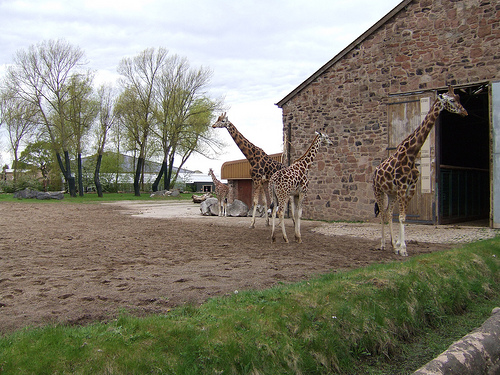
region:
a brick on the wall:
[335, 185, 357, 199]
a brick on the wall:
[337, 199, 342, 206]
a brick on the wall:
[343, 198, 354, 211]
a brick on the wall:
[311, 200, 322, 209]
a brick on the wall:
[317, 197, 331, 209]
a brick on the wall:
[356, 203, 369, 210]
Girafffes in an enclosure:
[209, 83, 466, 255]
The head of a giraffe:
[439, 85, 464, 119]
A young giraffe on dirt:
[260, 130, 334, 238]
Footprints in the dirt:
[13, 271, 153, 312]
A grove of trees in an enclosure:
[4, 38, 212, 196]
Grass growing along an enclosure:
[4, 239, 498, 374]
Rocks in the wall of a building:
[402, 20, 480, 64]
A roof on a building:
[65, 153, 205, 174]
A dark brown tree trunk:
[130, 157, 143, 200]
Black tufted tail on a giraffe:
[370, 200, 381, 222]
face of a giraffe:
[430, 80, 470, 116]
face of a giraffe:
[302, 120, 329, 156]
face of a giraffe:
[202, 105, 243, 130]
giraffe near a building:
[205, 163, 235, 213]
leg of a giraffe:
[391, 202, 414, 255]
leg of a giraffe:
[276, 201, 291, 266]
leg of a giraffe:
[291, 188, 302, 248]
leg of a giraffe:
[247, 186, 262, 229]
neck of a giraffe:
[410, 117, 434, 149]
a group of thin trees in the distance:
[0, 37, 226, 197]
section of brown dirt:
[1, 204, 444, 320]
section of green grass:
[3, 240, 498, 373]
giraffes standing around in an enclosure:
[203, 94, 470, 257]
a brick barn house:
[278, 0, 498, 223]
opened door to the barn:
[383, 85, 498, 225]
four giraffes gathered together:
[203, 90, 468, 257]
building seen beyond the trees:
[33, 153, 200, 183]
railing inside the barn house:
[437, 162, 488, 219]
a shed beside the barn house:
[218, 152, 282, 208]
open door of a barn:
[431, 74, 496, 229]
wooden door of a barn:
[383, 89, 440, 226]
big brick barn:
[272, 0, 499, 227]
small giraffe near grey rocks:
[202, 168, 234, 216]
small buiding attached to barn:
[217, 148, 287, 220]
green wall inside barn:
[433, 160, 488, 227]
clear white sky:
[1, 0, 409, 167]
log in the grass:
[12, 185, 70, 203]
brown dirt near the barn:
[0, 198, 465, 337]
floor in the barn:
[440, 210, 497, 230]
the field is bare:
[32, 208, 230, 309]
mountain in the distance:
[73, 142, 189, 172]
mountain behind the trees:
[17, 63, 193, 195]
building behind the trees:
[62, 162, 206, 193]